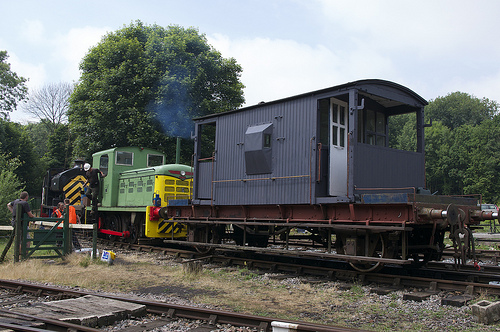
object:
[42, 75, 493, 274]
train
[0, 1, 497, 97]
sky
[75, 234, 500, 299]
tracks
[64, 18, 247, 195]
trees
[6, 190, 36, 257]
men